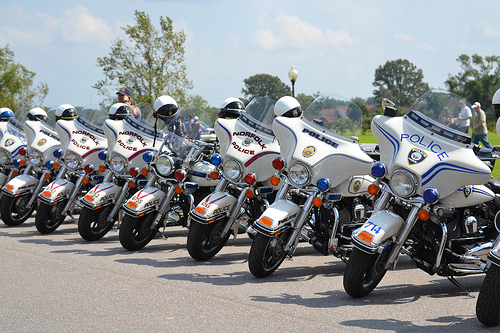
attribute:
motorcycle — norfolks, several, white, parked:
[249, 92, 382, 277]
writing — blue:
[401, 132, 450, 162]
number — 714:
[365, 220, 382, 235]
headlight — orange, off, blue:
[391, 170, 418, 198]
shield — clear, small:
[415, 88, 476, 135]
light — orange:
[366, 182, 380, 198]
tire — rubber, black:
[344, 245, 390, 295]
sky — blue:
[1, 0, 497, 111]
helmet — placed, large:
[153, 94, 179, 116]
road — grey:
[0, 215, 499, 332]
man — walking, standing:
[455, 100, 472, 132]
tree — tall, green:
[374, 58, 429, 116]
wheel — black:
[188, 217, 230, 259]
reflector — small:
[360, 230, 373, 243]